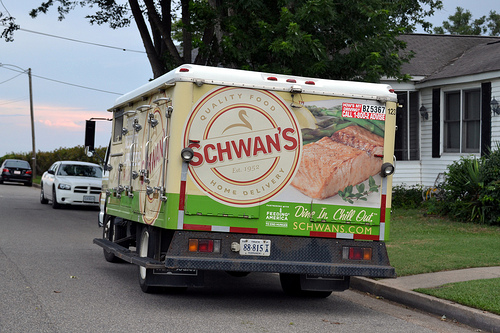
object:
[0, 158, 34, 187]
car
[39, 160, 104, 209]
car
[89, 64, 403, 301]
truck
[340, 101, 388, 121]
sign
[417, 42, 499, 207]
house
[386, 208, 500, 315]
grass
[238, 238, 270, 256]
license plate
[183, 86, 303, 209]
logo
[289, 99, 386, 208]
picture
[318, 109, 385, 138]
asparagus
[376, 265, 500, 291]
sidewalk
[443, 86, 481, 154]
window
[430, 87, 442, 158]
shutter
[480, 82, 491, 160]
shutter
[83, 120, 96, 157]
mirror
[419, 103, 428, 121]
lamp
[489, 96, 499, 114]
lamp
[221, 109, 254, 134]
swan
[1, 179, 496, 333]
road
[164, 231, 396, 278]
bumper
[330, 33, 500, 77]
roof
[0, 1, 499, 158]
sky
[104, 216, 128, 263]
tire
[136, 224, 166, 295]
tire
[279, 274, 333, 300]
tire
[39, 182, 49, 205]
tire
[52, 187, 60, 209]
tire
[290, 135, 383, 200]
salmon fillet